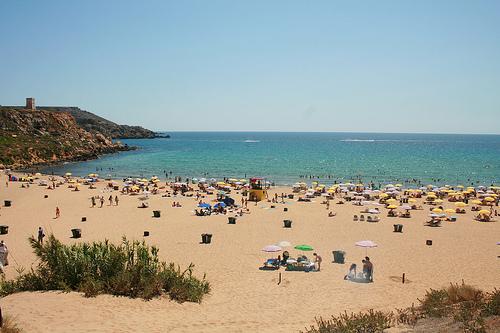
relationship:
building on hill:
[25, 97, 36, 108] [1, 107, 128, 169]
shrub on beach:
[2, 234, 211, 304] [0, 173, 499, 332]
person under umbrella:
[312, 252, 323, 271] [294, 243, 313, 251]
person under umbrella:
[361, 257, 372, 281] [354, 239, 377, 248]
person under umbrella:
[199, 208, 205, 215] [197, 202, 212, 208]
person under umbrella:
[272, 254, 282, 270] [260, 243, 283, 252]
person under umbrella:
[302, 255, 310, 263] [294, 243, 313, 251]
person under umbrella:
[481, 213, 489, 221] [477, 209, 491, 215]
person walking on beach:
[115, 195, 119, 206] [0, 173, 499, 332]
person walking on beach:
[108, 194, 114, 205] [0, 173, 499, 332]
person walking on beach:
[99, 196, 106, 207] [0, 173, 499, 332]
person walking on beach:
[91, 196, 97, 209] [0, 173, 499, 332]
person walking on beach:
[54, 206, 61, 219] [0, 173, 499, 332]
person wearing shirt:
[54, 206, 61, 219] [56, 209, 61, 214]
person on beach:
[54, 206, 61, 219] [0, 173, 499, 332]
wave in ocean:
[241, 138, 262, 144] [18, 131, 499, 188]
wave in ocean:
[335, 138, 376, 140] [18, 131, 499, 188]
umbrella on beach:
[275, 241, 294, 249] [0, 173, 499, 332]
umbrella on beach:
[399, 205, 411, 211] [0, 173, 499, 332]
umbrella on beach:
[428, 213, 439, 218] [0, 173, 499, 332]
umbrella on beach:
[386, 203, 395, 210] [0, 173, 499, 332]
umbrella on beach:
[407, 198, 417, 204] [0, 173, 499, 332]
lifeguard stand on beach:
[247, 177, 269, 200] [0, 173, 499, 332]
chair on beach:
[353, 214, 359, 221] [0, 173, 499, 332]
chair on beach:
[359, 215, 365, 222] [0, 173, 499, 332]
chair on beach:
[366, 216, 373, 223] [0, 173, 499, 332]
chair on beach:
[374, 217, 379, 222] [0, 173, 499, 332]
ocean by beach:
[18, 131, 499, 188] [0, 173, 499, 332]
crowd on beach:
[4, 176, 499, 284] [0, 173, 499, 332]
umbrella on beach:
[260, 243, 283, 252] [0, 173, 499, 332]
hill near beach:
[1, 107, 128, 169] [0, 173, 499, 332]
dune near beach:
[0, 279, 500, 331] [0, 173, 499, 332]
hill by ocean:
[1, 107, 128, 169] [18, 131, 499, 188]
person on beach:
[91, 196, 97, 209] [0, 173, 499, 332]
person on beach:
[99, 196, 106, 207] [0, 173, 499, 332]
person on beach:
[108, 194, 114, 205] [0, 173, 499, 332]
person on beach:
[115, 195, 119, 206] [0, 173, 499, 332]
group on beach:
[264, 251, 323, 273] [0, 173, 499, 332]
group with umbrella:
[264, 251, 323, 273] [260, 243, 283, 252]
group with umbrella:
[264, 251, 323, 273] [275, 241, 294, 249]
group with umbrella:
[264, 251, 323, 273] [294, 243, 313, 251]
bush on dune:
[398, 278, 499, 332] [0, 279, 500, 331]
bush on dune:
[302, 310, 396, 332] [0, 279, 500, 331]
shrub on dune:
[2, 234, 211, 304] [0, 279, 500, 331]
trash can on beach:
[5, 199, 11, 207] [0, 173, 499, 332]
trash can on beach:
[1, 226, 8, 235] [0, 173, 499, 332]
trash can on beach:
[228, 217, 237, 225] [0, 173, 499, 332]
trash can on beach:
[152, 210, 160, 217] [0, 173, 499, 332]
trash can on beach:
[283, 219, 292, 229] [0, 173, 499, 332]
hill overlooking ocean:
[1, 107, 128, 169] [18, 131, 499, 188]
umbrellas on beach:
[288, 183, 499, 228] [0, 173, 499, 332]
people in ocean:
[296, 172, 498, 186] [18, 131, 499, 188]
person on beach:
[199, 208, 205, 215] [0, 173, 499, 332]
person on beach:
[312, 252, 323, 271] [0, 173, 499, 332]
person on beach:
[302, 255, 310, 263] [0, 173, 499, 332]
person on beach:
[272, 254, 282, 270] [0, 173, 499, 332]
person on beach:
[481, 213, 489, 221] [0, 173, 499, 332]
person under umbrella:
[402, 211, 410, 220] [399, 205, 411, 211]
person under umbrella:
[464, 194, 469, 202] [461, 189, 470, 196]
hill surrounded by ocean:
[1, 107, 128, 169] [18, 131, 499, 188]